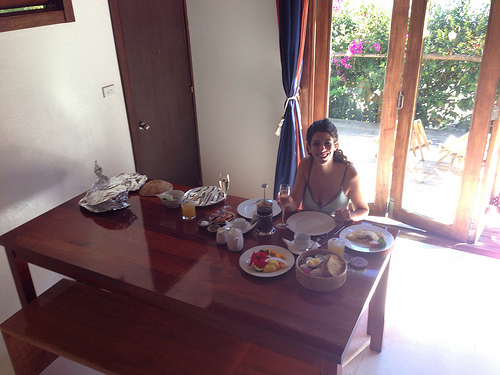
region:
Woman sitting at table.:
[280, 115, 374, 225]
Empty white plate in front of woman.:
[283, 205, 335, 242]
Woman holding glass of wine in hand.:
[273, 179, 292, 229]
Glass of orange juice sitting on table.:
[179, 195, 203, 221]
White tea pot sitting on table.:
[226, 223, 247, 255]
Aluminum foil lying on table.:
[78, 154, 147, 222]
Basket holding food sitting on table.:
[295, 245, 352, 292]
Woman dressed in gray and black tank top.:
[300, 155, 356, 212]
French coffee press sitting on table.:
[251, 178, 283, 236]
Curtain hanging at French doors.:
[264, 3, 314, 199]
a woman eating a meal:
[273, 110, 386, 296]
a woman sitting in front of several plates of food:
[243, 118, 394, 299]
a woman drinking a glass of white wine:
[278, 113, 377, 230]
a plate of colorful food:
[238, 244, 295, 281]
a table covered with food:
[89, 195, 396, 340]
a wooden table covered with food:
[90, 177, 401, 347]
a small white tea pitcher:
[220, 225, 240, 250]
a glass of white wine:
[276, 181, 293, 231]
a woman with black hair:
[303, 120, 353, 168]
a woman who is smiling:
[299, 117, 343, 167]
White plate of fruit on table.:
[239, 247, 291, 279]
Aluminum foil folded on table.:
[78, 167, 142, 222]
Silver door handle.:
[138, 120, 150, 132]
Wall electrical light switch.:
[100, 84, 119, 96]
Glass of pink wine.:
[277, 188, 289, 230]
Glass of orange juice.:
[178, 199, 195, 218]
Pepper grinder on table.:
[257, 180, 272, 236]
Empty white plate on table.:
[288, 209, 333, 236]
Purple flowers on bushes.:
[331, 39, 382, 77]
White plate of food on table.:
[342, 222, 392, 255]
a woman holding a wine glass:
[267, 109, 347, 214]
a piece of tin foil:
[78, 154, 143, 231]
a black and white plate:
[188, 179, 225, 206]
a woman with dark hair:
[301, 114, 341, 163]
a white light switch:
[95, 67, 127, 103]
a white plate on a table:
[284, 206, 340, 235]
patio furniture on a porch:
[403, 115, 465, 182]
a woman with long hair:
[307, 117, 352, 179]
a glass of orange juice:
[172, 194, 202, 226]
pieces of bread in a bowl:
[311, 247, 354, 291]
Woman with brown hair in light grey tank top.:
[280, 118, 370, 221]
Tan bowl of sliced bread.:
[295, 246, 348, 292]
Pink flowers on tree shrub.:
[331, 3, 385, 117]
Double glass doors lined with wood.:
[309, 0, 499, 241]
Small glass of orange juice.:
[180, 200, 197, 221]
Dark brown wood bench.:
[0, 278, 339, 373]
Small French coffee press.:
[250, 183, 277, 236]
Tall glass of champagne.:
[277, 182, 289, 230]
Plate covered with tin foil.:
[180, 184, 225, 205]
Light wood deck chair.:
[410, 115, 435, 167]